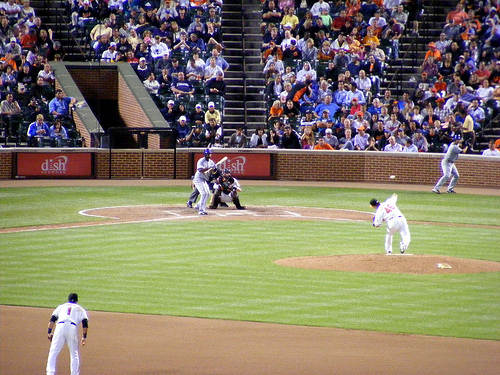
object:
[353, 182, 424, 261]
person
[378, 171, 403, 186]
ball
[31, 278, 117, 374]
player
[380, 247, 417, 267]
mound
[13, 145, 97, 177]
sign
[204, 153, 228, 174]
bat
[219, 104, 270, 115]
stairs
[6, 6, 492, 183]
spectator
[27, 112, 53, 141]
people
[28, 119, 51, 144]
shirts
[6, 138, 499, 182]
wall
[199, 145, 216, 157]
helmet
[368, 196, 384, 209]
hat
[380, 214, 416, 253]
pants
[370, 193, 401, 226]
shirt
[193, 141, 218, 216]
person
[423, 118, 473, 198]
person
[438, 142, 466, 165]
shirt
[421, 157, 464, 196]
gray pant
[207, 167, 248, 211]
catcher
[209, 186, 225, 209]
shin guards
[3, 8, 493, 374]
game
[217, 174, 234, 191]
catch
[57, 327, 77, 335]
white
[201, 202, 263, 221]
home plate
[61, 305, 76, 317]
1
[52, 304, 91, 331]
jersey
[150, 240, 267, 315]
grass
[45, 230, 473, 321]
outfield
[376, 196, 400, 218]
46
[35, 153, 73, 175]
dish logo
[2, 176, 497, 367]
field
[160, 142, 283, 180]
deck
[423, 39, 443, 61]
person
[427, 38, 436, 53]
orange cap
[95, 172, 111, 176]
bricks